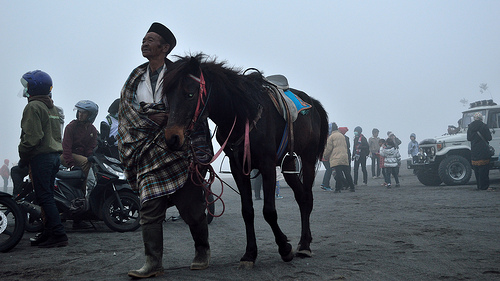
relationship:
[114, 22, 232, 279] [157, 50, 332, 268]
man with horse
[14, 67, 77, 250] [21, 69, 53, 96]
man wearing helmet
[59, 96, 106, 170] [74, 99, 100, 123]
man wearing helmet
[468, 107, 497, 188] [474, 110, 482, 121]
person wearing hat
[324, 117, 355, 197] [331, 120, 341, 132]
person wearing hat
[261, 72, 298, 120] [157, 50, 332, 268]
saddle on horse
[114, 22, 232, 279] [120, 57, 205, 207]
man in blanket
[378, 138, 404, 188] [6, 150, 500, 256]
person on beach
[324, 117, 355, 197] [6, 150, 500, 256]
person on beach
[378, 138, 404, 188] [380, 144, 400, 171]
person in coat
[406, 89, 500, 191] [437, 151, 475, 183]
truck has tire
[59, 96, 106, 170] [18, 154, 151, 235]
man on motorcycle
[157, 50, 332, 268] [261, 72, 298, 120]
horse has saddle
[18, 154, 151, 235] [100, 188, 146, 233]
motorcycle has wheel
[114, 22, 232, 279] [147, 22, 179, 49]
man wearing hat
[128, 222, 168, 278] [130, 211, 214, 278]
boot in pair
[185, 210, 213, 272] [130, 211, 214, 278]
boot in pair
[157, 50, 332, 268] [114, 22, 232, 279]
horse by man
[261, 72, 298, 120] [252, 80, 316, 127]
saddle on back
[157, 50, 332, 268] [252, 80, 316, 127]
horse has back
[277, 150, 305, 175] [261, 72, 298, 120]
stirrup on saddle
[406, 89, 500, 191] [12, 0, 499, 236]
jeep in background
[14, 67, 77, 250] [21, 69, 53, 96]
person has helmet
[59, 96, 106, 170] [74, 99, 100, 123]
person has helmet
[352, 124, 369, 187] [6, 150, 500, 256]
person on sand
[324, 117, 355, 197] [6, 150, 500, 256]
person on sand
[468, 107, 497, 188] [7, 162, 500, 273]
person on sand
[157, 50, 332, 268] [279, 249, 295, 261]
horse has hoof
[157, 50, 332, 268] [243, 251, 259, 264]
horse has hoof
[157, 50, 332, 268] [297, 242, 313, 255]
horse has hoof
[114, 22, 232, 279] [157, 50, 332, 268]
man leading horse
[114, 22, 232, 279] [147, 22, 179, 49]
man has hat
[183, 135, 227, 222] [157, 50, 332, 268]
rope connected to horse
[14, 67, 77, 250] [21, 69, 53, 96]
person wearing helmet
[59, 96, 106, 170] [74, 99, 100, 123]
person wearing helmet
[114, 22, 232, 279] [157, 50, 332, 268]
man walking horse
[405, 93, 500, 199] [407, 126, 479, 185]
jeep has end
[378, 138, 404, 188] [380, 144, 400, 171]
person wearing jacket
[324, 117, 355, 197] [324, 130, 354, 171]
person wearing jacket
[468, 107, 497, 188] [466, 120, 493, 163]
person wearing jacket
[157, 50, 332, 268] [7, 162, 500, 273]
horse on sand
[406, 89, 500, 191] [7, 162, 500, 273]
vehicle on sand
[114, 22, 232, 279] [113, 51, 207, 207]
man keeping warm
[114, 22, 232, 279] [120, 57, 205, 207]
man with blanket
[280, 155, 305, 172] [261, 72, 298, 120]
strap on saddle